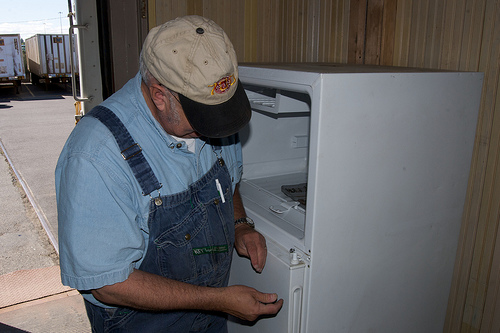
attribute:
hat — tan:
[136, 24, 289, 141]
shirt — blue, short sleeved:
[66, 139, 148, 271]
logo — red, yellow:
[209, 75, 236, 96]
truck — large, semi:
[22, 28, 81, 90]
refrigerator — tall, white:
[224, 60, 489, 330]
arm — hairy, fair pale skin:
[61, 157, 226, 313]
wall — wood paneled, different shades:
[144, 1, 496, 331]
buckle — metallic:
[143, 182, 164, 204]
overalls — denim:
[83, 103, 235, 331]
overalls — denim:
[106, 153, 263, 280]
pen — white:
[213, 177, 225, 202]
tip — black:
[195, 25, 206, 35]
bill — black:
[193, 94, 254, 136]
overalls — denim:
[45, 79, 287, 331]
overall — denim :
[81, 104, 234, 331]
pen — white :
[214, 177, 226, 200]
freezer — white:
[210, 56, 488, 331]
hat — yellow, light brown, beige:
[142, 12, 254, 140]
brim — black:
[180, 77, 253, 142]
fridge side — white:
[314, 67, 490, 331]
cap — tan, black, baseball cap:
[136, 17, 307, 185]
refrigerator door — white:
[223, 228, 307, 327]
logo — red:
[210, 70, 238, 95]